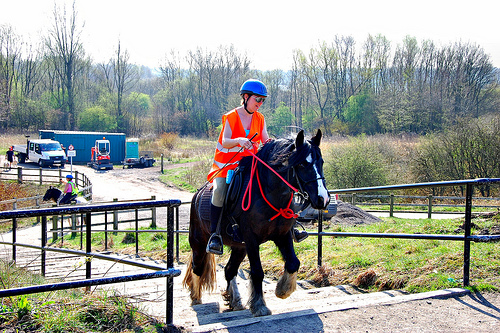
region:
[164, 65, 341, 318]
woman riding a horse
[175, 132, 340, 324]
horse walking up a flight of stairs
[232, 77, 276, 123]
woman wearing a blue safet riding helmet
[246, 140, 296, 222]
red reigns on horse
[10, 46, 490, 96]
tall trees with no leaves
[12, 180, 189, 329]
black metal railings along stair case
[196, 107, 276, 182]
woman wearing an orange safety vest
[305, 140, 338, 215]
white patch on horses face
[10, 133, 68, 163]
white truck on dirt road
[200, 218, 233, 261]
womans foot in stirrups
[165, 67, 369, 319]
show horse and rider moving up staircase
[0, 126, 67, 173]
white utility truck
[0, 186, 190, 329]
metal fence painted black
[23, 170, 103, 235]
horse and rider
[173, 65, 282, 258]
human wearing protective equipment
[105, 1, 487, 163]
row of green trees shot against a blue sky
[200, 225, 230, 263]
stirrup used for horse riding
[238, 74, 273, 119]
human wearing helmet and sunglasses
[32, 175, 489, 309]
fenced in area protecting green grass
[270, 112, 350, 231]
head of a show horse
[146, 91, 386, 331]
Person riding a horse up stairs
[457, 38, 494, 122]
Brown tree with no leaves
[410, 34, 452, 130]
Brown tree with no leaves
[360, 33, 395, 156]
Brown tree with no leaves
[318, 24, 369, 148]
Brown tree with no leaves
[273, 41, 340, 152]
Brown tree with no leaves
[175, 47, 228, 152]
Brown tree with no leaves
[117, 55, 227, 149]
Brown tree with no leaves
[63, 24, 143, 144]
Brown tree with no leaves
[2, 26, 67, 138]
Brown tree with no leaves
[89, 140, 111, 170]
A forklift parked outside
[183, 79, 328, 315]
A woman on a horse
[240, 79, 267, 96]
A helmet worn by a lady on a horse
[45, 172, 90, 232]
A person riding a horse on a dirt pathway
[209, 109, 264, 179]
An orange construction jacket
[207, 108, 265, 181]
An orange construction vest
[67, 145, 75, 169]
A street sign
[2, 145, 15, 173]
A man attending some labor work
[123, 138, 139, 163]
A porter john outside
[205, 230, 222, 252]
A shoe worn on right foot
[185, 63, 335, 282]
person riding a horse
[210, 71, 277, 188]
person wearing an orange and white safety vest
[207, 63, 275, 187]
person wearing a blue riding helmet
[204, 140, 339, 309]
black and white horse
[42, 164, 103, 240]
person riding a horse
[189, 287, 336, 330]
shadow of a horse on steps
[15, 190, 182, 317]
metal stairway railing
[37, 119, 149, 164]
storage building and trucks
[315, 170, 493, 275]
black metal stairway railing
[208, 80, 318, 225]
person holding red horse reins